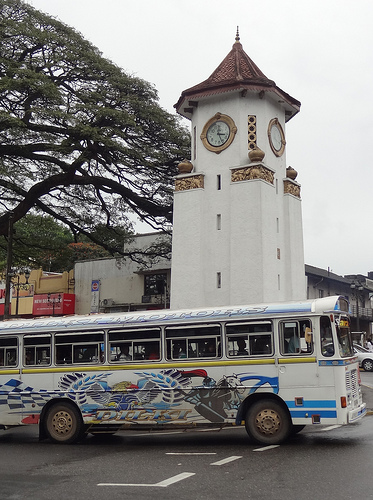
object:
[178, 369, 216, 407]
knight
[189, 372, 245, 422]
horse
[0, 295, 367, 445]
bus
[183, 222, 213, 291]
wall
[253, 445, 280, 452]
line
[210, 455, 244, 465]
line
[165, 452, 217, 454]
line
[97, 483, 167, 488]
line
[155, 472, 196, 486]
lines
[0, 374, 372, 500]
ground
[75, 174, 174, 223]
bare branch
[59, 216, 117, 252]
bare branch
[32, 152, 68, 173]
bare branch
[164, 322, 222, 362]
passenger window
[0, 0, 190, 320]
large tree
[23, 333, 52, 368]
window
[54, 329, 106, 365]
window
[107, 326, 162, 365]
window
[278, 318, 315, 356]
window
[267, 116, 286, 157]
clock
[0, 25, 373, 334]
building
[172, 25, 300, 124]
roof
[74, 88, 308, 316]
white building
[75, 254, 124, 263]
roof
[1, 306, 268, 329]
bus company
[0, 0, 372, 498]
area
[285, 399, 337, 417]
blue lines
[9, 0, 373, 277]
sky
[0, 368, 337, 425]
design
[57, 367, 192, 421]
image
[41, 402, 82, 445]
tire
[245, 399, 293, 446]
tire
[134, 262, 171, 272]
line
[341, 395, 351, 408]
light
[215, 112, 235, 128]
ornate frame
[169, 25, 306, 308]
clock tower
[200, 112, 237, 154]
clock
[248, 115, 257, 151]
design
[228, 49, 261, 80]
part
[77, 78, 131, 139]
part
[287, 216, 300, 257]
part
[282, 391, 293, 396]
part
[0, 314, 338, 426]
side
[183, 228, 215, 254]
part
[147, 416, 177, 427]
edge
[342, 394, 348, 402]
part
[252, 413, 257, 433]
edge